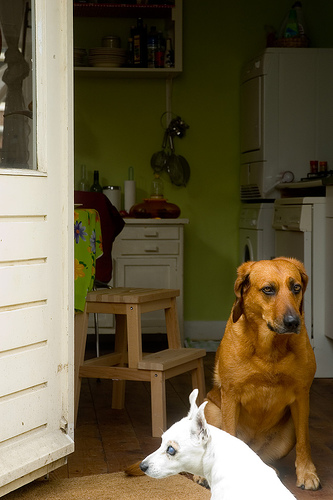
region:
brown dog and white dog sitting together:
[130, 248, 320, 498]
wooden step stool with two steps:
[86, 278, 215, 429]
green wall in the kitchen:
[77, 2, 237, 316]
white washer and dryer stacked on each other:
[231, 56, 275, 379]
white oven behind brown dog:
[268, 188, 329, 377]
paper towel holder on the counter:
[121, 160, 139, 216]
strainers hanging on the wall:
[151, 114, 195, 186]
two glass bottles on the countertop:
[74, 162, 105, 210]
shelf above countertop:
[79, 1, 184, 79]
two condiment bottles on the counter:
[304, 159, 328, 178]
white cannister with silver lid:
[101, 184, 122, 216]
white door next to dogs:
[0, 0, 78, 470]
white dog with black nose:
[137, 388, 293, 498]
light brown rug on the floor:
[36, 459, 211, 498]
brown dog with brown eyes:
[125, 258, 329, 499]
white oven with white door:
[272, 195, 329, 373]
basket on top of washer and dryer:
[258, 5, 307, 46]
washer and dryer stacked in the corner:
[238, 48, 329, 283]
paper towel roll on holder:
[121, 166, 138, 215]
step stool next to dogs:
[81, 278, 205, 439]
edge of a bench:
[147, 369, 151, 385]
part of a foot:
[296, 481, 303, 482]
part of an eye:
[168, 431, 176, 458]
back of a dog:
[236, 465, 241, 490]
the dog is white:
[136, 388, 295, 497]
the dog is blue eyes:
[165, 446, 175, 455]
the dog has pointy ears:
[189, 391, 212, 441]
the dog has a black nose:
[138, 459, 148, 471]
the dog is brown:
[206, 256, 322, 490]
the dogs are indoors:
[136, 257, 319, 499]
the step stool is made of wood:
[83, 290, 207, 435]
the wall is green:
[71, 0, 238, 318]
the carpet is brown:
[5, 468, 210, 497]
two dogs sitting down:
[131, 256, 317, 498]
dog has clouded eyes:
[167, 447, 177, 456]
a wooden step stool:
[83, 286, 203, 432]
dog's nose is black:
[282, 314, 299, 333]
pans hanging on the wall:
[147, 111, 192, 191]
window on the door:
[0, 3, 37, 164]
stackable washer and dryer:
[235, 50, 324, 268]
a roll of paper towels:
[125, 176, 135, 210]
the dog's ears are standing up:
[179, 389, 208, 444]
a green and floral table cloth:
[74, 208, 102, 305]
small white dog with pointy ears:
[139, 388, 285, 498]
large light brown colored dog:
[222, 253, 315, 402]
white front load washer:
[236, 207, 266, 257]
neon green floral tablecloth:
[76, 210, 91, 279]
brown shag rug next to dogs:
[77, 469, 139, 499]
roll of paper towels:
[123, 169, 136, 205]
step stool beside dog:
[72, 284, 209, 437]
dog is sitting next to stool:
[191, 254, 320, 489]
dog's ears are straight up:
[138, 386, 210, 497]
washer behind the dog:
[231, 201, 259, 259]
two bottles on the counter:
[76, 160, 102, 196]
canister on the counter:
[100, 178, 120, 213]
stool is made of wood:
[63, 277, 208, 436]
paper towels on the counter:
[124, 159, 136, 213]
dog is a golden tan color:
[198, 249, 323, 490]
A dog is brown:
[195, 244, 323, 490]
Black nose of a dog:
[273, 305, 300, 333]